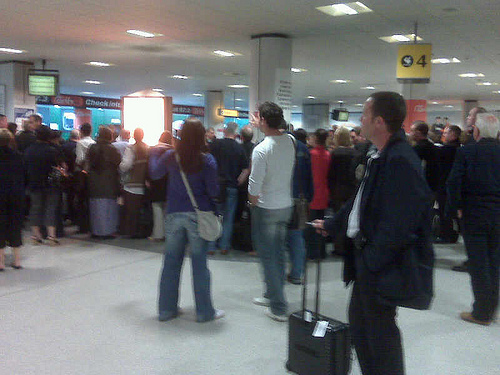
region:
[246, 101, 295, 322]
a man in a white shirt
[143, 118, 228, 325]
a woman carrying a white bag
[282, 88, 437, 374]
a man with suitcase in hand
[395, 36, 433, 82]
a yellow sign with the number 4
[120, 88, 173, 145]
a brightly lit sign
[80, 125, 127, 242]
a woman wearing a dress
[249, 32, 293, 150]
a large pillar with sign pasted to it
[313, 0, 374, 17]
a recessed ceiling light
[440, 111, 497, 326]
a man with balding head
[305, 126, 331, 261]
a person dressed in a red jacket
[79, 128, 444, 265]
People standing in an airport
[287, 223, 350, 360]
A pull along suitcase on the floor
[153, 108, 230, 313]
The girl is wearing a blue shirt and jeans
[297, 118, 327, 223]
This lady is wearing a red sweater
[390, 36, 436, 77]
The number four on the ceiling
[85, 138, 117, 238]
This woman is in a long skirt and coat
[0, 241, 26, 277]
This woman is wearing short pants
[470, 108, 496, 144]
This man has white hair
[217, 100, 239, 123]
A sign that is lit up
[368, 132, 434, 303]
Man is wearing a darl colored jacket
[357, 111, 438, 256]
man in black jacket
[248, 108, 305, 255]
man in white shirt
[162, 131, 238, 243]
woman in blue shirt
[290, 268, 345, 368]
black case on ground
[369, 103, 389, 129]
left ear on man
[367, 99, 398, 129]
brown hair on man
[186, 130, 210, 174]
brown hair on woman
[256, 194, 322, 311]
man in blue jeans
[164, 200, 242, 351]
woman in blue jeans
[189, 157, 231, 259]
woman with white bag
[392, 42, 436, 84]
Yellow and black sign hanging from ceiling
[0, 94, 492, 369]
The people are standing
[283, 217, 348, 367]
The suit case is black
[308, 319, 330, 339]
White tag on suit case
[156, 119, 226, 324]
Woman holding a white bag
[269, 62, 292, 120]
Large white sign on column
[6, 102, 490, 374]
Large crowd of people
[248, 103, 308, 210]
Man wearing a white sweater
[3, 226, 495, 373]
The floor is white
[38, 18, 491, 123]
Row of lights on the ceiling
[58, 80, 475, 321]
people that are standing inside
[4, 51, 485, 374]
people standing in a group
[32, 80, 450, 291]
a woman with a purse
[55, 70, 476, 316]
group of people standing in a station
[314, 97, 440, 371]
a man wearing a jacket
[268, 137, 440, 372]
a man with a suitcase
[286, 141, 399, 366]
a man with a black suitcase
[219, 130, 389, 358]
a black suitcase rolling on the floor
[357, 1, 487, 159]
number 4 sign hanging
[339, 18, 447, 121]
a sign hanging from the ceiling